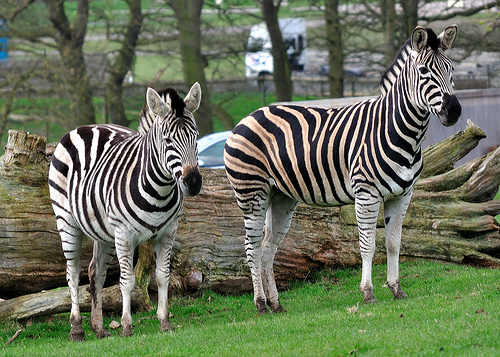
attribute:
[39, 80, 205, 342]
zebra — black, white, standing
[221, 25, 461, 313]
zebra — standing, black, white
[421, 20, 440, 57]
mane — black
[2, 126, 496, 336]
tree trunk — fallen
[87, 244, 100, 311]
tail — long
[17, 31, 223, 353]
zebra — black, white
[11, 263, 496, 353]
yard — green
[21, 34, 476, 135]
trees — leafless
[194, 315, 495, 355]
grass — green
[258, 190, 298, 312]
leg — white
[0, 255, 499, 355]
patch — green